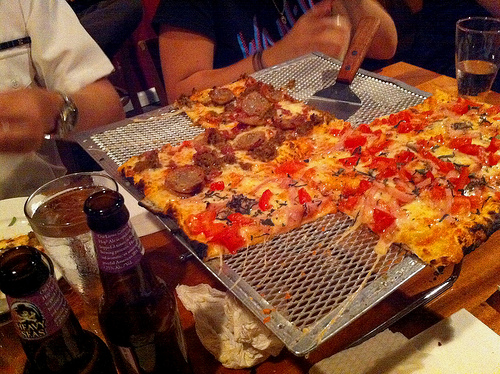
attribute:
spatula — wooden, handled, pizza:
[305, 13, 382, 118]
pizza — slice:
[180, 72, 333, 132]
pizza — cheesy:
[287, 97, 472, 249]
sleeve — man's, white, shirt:
[17, 1, 116, 97]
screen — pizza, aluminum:
[252, 236, 427, 311]